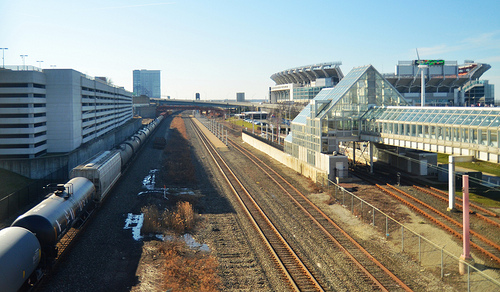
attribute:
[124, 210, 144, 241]
puddle — small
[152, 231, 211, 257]
puddle — small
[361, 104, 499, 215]
monorail — glass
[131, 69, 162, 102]
buildling — tall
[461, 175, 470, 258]
pole — pink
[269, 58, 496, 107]
stadium — white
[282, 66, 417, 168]
buildling — glass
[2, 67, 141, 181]
parking lot — multi-level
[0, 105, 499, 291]
ground — dirty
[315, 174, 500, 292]
fence — chain link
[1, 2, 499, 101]
sky — clear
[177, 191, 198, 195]
puddle — small